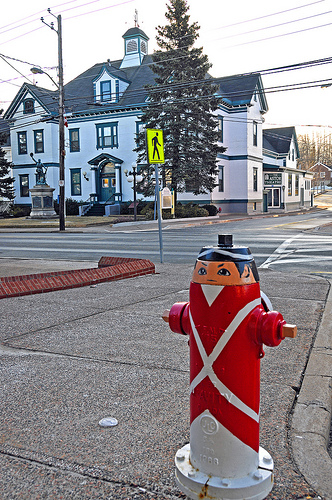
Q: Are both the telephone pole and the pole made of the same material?
A: No, the telephone pole is made of wood and the pole is made of metal.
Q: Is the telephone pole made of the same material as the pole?
A: No, the telephone pole is made of wood and the pole is made of metal.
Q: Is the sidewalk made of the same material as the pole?
A: No, the sidewalk is made of cement and the pole is made of metal.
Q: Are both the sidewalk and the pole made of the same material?
A: No, the sidewalk is made of cement and the pole is made of metal.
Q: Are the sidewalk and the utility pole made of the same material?
A: No, the sidewalk is made of concrete and the utility pole is made of wood.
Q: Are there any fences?
A: No, there are no fences.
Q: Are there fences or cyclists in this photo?
A: No, there are no fences or cyclists.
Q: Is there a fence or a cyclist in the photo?
A: No, there are no fences or cyclists.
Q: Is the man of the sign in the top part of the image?
A: Yes, the man is in the top of the image.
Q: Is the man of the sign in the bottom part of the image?
A: No, the man is in the top of the image.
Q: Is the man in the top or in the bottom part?
A: The man is in the top of the image.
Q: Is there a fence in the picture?
A: No, there are no fences.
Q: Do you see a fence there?
A: No, there are no fences.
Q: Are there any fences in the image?
A: No, there are no fences.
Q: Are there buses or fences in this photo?
A: No, there are no fences or buses.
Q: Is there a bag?
A: No, there are no bags.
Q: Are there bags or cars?
A: No, there are no bags or cars.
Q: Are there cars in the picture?
A: No, there are no cars.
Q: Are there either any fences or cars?
A: No, there are no cars or fences.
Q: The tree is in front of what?
A: The tree is in front of the house.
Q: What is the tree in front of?
A: The tree is in front of the house.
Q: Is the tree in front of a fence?
A: No, the tree is in front of the house.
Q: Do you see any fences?
A: No, there are no fences.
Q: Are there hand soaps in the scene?
A: No, there are no hand soaps.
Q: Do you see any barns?
A: No, there are no barns.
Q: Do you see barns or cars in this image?
A: No, there are no barns or cars.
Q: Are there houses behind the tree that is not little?
A: Yes, there is a house behind the tree.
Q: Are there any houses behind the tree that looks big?
A: Yes, there is a house behind the tree.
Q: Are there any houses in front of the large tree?
A: No, the house is behind the tree.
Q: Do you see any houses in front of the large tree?
A: No, the house is behind the tree.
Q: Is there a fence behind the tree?
A: No, there is a house behind the tree.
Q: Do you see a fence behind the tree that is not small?
A: No, there is a house behind the tree.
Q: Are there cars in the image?
A: No, there are no cars.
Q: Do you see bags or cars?
A: No, there are no cars or bags.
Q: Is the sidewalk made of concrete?
A: Yes, the sidewalk is made of concrete.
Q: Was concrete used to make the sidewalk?
A: Yes, the sidewalk is made of concrete.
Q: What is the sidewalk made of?
A: The sidewalk is made of concrete.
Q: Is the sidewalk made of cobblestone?
A: No, the sidewalk is made of concrete.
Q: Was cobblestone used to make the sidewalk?
A: No, the sidewalk is made of concrete.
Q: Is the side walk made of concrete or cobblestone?
A: The side walk is made of concrete.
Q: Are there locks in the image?
A: No, there are no locks.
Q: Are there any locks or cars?
A: No, there are no locks or cars.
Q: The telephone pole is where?
A: The telephone pole is on the sidewalk.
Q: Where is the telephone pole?
A: The telephone pole is on the sidewalk.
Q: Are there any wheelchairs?
A: No, there are no wheelchairs.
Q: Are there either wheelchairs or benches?
A: No, there are no wheelchairs or benches.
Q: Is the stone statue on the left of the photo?
A: Yes, the statue is on the left of the image.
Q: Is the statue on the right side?
A: No, the statue is on the left of the image.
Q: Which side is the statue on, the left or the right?
A: The statue is on the left of the image.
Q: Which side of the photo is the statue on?
A: The statue is on the left of the image.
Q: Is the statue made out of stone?
A: Yes, the statue is made of stone.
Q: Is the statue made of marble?
A: No, the statue is made of stone.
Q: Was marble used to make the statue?
A: No, the statue is made of stone.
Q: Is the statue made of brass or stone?
A: The statue is made of stone.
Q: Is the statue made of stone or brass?
A: The statue is made of stone.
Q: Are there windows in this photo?
A: Yes, there is a window.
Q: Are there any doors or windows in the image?
A: Yes, there is a window.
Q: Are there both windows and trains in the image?
A: No, there is a window but no trains.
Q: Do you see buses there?
A: No, there are no buses.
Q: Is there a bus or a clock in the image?
A: No, there are no buses or clocks.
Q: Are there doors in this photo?
A: Yes, there is a door.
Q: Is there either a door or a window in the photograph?
A: Yes, there is a door.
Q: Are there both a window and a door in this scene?
A: Yes, there are both a door and a window.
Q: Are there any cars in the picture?
A: No, there are no cars.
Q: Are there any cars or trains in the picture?
A: No, there are no cars or trains.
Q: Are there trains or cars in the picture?
A: No, there are no cars or trains.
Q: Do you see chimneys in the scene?
A: No, there are no chimneys.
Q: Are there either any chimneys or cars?
A: No, there are no chimneys or cars.